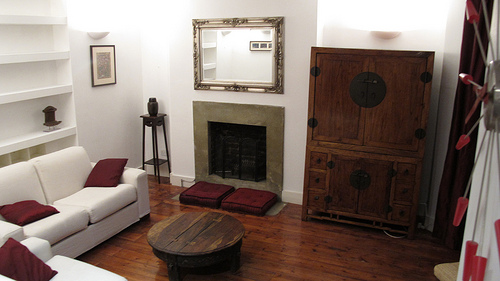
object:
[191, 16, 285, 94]
mirror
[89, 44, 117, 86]
framed picture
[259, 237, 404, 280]
floor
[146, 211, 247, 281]
table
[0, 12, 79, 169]
shelf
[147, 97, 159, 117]
vase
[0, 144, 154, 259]
sofa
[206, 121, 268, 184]
fireplace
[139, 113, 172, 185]
stand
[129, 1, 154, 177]
corner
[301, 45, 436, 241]
cabinet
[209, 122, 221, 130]
part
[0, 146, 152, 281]
couch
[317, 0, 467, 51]
wall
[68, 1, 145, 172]
wall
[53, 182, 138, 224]
cushion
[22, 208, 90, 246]
cushion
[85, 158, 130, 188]
pillow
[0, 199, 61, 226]
pillow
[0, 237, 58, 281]
pillow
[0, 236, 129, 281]
sofa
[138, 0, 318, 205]
wall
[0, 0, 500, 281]
living room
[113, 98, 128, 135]
part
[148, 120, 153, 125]
part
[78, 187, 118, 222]
part